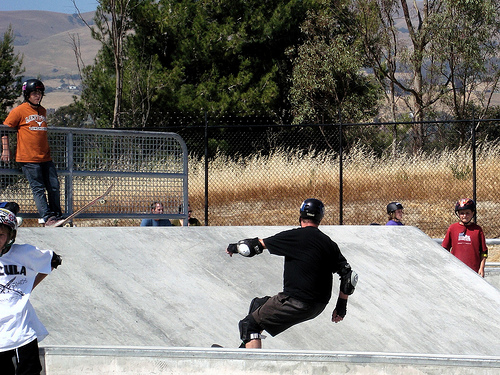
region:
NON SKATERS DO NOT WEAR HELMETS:
[138, 197, 203, 212]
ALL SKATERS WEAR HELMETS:
[284, 189, 342, 239]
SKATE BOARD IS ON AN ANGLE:
[34, 172, 128, 226]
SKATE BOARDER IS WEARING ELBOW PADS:
[218, 230, 370, 288]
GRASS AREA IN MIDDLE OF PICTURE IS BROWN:
[0, 156, 495, 233]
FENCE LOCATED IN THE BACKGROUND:
[0, 95, 498, 242]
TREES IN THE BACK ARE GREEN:
[0, 52, 497, 145]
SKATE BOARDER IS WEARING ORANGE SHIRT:
[5, 90, 57, 161]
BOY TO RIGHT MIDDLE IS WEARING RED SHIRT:
[440, 197, 488, 273]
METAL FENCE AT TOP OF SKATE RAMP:
[0, 127, 197, 222]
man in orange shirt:
[17, 44, 125, 252]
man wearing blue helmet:
[5, 62, 70, 109]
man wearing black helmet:
[251, 161, 363, 265]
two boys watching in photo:
[357, 177, 489, 278]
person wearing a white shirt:
[15, 260, 57, 372]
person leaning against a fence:
[10, 85, 197, 212]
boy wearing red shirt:
[427, 184, 487, 291]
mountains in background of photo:
[5, 7, 200, 122]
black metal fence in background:
[22, 92, 467, 236]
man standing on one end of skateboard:
[12, 80, 166, 240]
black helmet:
[283, 173, 349, 248]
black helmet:
[271, 134, 365, 270]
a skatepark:
[16, 37, 496, 370]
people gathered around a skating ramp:
[2, 72, 498, 368]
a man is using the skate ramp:
[208, 196, 365, 353]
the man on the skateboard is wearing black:
[208, 170, 373, 354]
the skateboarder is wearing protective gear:
[201, 194, 363, 352]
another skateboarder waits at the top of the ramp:
[8, 72, 213, 224]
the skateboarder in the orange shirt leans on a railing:
[7, 73, 204, 223]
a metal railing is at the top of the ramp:
[14, 114, 219, 216]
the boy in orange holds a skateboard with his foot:
[3, 71, 142, 228]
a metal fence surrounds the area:
[58, 107, 499, 224]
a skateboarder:
[213, 155, 395, 342]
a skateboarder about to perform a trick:
[200, 175, 364, 372]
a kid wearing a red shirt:
[437, 220, 496, 265]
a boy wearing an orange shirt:
[3, 102, 62, 157]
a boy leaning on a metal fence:
[3, 79, 90, 213]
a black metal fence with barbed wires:
[203, 108, 280, 223]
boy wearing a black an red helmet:
[444, 189, 484, 222]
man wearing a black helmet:
[295, 183, 328, 230]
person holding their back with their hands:
[1, 205, 68, 373]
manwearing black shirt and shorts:
[251, 224, 348, 346]